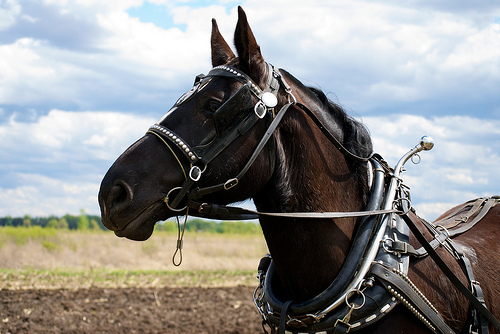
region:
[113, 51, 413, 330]
the hors is brown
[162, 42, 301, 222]
the horse is wearing straps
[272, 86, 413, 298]
the horse is wearing straps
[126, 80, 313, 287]
the horse is wearing straps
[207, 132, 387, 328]
the horse is wearing straps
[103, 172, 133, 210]
The nose of the horse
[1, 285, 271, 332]
Dirt below the horse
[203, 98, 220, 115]
The left eye of the horse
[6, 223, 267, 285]
A grassy field next to the horse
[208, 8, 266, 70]
The ears of the horse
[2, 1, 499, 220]
The sky above the horse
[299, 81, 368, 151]
The mane of the horse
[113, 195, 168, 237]
The mouth of the horse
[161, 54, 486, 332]
Reigns on the horse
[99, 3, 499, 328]
A horse near a grassy field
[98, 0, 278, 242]
Head of brown horse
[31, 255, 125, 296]
Field area behind horse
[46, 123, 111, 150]
white billowey clouds in sky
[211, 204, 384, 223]
Rein to guide horse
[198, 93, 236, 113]
Eye of brown horse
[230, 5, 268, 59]
Ear of brown horse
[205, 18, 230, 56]
Ear of brown horse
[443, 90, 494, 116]
Blue sky showing through clouds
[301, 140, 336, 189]
Part of neck of horse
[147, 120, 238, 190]
Part of horse harness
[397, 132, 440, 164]
Chrome fittings on the horse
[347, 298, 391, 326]
White small rope trim on the horse fittings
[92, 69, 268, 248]
Dark colored face horse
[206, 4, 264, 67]
Brown ears on the horse.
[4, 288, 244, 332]
Newly plowed ground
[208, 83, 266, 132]
Blinders on the horse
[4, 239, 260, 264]
Wheat field in the distance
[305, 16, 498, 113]
Partly cloudy sky in the distance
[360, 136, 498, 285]
Plowing rigging on the horse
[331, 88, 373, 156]
Black mane on the horse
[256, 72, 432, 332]
Black yoke on the horse.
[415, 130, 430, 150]
Silver ball on the end of the yoke post.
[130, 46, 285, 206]
Black studded bridle on the horse.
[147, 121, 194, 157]
Silver studs on the leather strip.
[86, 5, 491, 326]
Brown horse in the forefront.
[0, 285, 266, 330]
Dark brown plowed dirt.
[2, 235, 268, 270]
Long brown grass in the background.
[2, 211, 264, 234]
Green trees in the background.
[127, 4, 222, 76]
White clouds in the sky.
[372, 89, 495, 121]
Blue sky in the background.